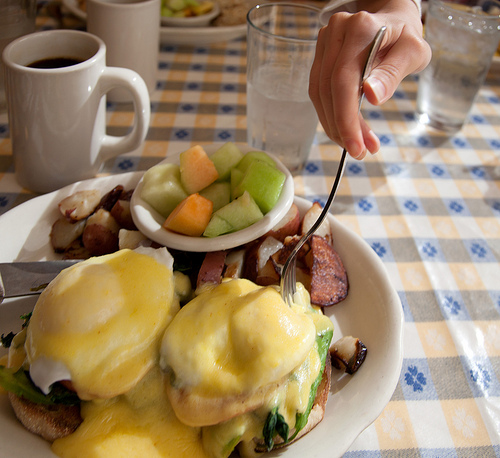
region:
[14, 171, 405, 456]
a plate full of food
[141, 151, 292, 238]
a small bowl of fruit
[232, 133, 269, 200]
a small chunk of honeydew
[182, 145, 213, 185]
a small chunk of cantaloupe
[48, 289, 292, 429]
two pieces of eggs benedict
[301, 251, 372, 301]
a piece of sliced sausage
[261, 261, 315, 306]
the end of a fork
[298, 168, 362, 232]
the handle of a fork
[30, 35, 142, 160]
a small cup of coffee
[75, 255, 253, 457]
Food is on the plate.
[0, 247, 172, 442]
Eggs benedict is on the plate.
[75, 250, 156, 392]
The egg is covered with hollandaise sauce.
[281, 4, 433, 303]
The hand holds a fork.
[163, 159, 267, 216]
Fruit is in the bowl.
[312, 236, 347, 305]
Potatoes are on the plate.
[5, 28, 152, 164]
A coffee cup is on the table.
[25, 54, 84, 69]
The cup contains coffee.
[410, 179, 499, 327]
The tablecloth is patterned.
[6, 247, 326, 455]
Eggs on a burger bun.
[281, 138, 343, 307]
The fork digs in.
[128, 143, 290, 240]
A fruit salad in a bowl.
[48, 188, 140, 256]
Potatoes fried sit beside the fruit.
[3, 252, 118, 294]
A knife rests on the plate.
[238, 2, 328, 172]
A half drank glass of ice water.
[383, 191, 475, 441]
A blue and yellow checked table cloth.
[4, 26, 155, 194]
A cup of coffee.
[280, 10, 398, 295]
The hand holds the fork.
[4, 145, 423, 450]
A plate of food.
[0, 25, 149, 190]
a white mug on a table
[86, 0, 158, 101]
a white mug on a table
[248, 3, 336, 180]
a glass on a table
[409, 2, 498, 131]
a glass on a table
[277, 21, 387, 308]
a person holding a fork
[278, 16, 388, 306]
a person holding a metal fork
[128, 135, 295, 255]
a small bowl of fruit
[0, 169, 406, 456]
a large plate of food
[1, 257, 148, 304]
a knife utensil on a plate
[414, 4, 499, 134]
a glass of water on a table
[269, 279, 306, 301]
The tip of the fork in the food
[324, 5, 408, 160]
The hand that is holding the fork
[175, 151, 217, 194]
orange melon in a bowl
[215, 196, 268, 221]
green melon that is in a bowl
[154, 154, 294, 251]
Orange and green melon that is in a bowl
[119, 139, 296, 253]
The white bowl that is holding melon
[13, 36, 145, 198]
A white coffee mug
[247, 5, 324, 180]
A glass that has water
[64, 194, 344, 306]
Potatoes that are on the plate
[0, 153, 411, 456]
a white plate of food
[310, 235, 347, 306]
a roasted potato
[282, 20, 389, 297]
a tall silver fork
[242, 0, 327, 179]
a tall glass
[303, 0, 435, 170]
the hand of a woman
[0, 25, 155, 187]
a white coffee mug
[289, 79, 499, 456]
a yellow, blue and white tablecloth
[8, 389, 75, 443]
a piece of bread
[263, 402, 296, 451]
a green piece of lettuce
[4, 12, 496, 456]
A yellow, blue, and white designed tablecloth.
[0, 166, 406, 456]
A round white plate.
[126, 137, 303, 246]
A small white bowl.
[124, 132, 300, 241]
A bowl of cut fruit.